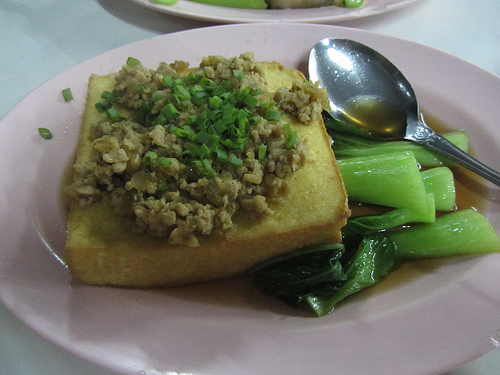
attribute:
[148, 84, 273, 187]
seasoning — green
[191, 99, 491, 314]
food — cooked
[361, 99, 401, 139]
spoon — silver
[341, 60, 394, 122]
spoon — metal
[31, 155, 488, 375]
plate — white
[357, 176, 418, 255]
vegetable — leafy and green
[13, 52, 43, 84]
table top — blue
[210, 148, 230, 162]
onion — green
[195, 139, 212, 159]
onion — green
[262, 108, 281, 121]
onion — green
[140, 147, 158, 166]
onion — green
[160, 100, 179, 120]
onion — green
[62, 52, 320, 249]
meat — ground, brown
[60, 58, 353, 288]
bread piece — thick, sliced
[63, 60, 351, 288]
sandwich — open faced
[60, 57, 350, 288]
meal — breaded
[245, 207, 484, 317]
vegetable — green, leafy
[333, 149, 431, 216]
vegetable — green, leafy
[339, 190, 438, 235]
vegetable — green, leafy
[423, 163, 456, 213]
vegetable — green, leafy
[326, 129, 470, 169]
vegetable — green, leafy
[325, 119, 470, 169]
vegetable — green, leafy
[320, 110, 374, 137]
vegetable — green, leafy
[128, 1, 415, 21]
plate — filled, white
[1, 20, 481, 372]
plate — white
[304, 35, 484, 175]
spoon — silver, gray, metal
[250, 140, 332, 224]
bread — sliced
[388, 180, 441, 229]
food — green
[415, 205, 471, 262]
food — green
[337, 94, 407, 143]
broth — small in amount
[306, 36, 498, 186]
spoon — silver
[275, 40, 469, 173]
spoon — silver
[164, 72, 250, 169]
chives — chopped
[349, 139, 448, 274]
vegetables — green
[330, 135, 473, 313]
chard — green, white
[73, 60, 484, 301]
food — vegetarian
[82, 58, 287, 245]
food — a piece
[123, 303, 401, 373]
plate — white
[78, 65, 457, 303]
food — underneath